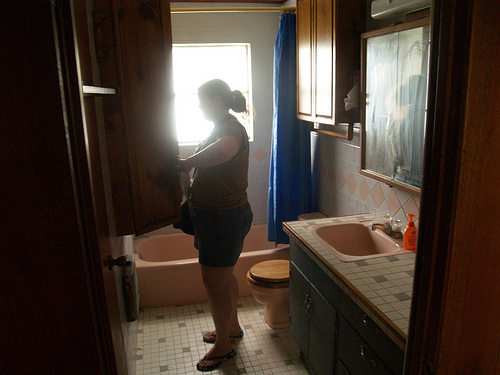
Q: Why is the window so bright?
A: Sunny outside.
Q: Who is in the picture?
A: A woman.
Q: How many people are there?
A: One.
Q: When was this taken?
A: During the day.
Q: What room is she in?
A: Bathroom.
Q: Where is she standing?
A: In front of the cabinet.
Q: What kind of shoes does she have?
A: Flip flops.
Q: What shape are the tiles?
A: Square.